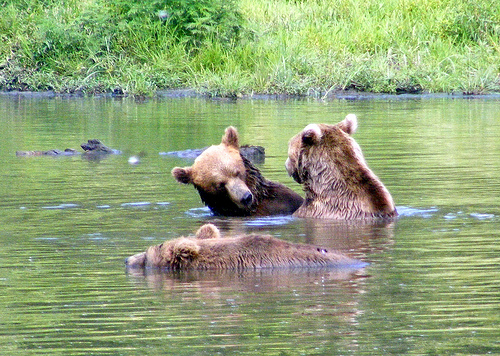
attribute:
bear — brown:
[278, 112, 395, 232]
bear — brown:
[278, 108, 393, 268]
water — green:
[222, 104, 318, 132]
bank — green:
[131, 43, 447, 104]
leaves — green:
[145, 0, 250, 80]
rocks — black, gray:
[65, 129, 137, 186]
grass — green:
[196, 37, 372, 89]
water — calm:
[24, 112, 153, 197]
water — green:
[0, 95, 499, 354]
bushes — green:
[185, 9, 257, 54]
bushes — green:
[87, 15, 163, 65]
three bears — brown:
[120, 111, 410, 298]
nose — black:
[240, 190, 255, 207]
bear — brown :
[107, 108, 470, 322]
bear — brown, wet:
[170, 126, 303, 217]